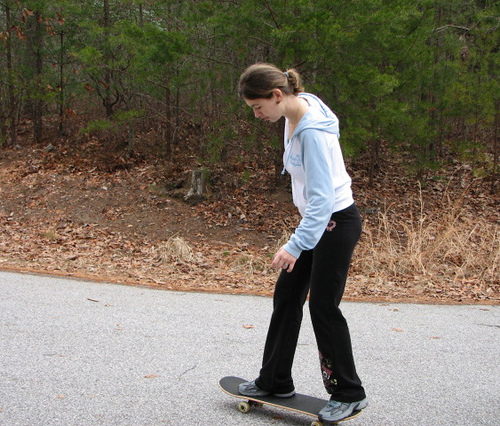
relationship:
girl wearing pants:
[235, 56, 417, 347] [228, 216, 402, 371]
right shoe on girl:
[235, 374, 294, 396] [235, 56, 365, 426]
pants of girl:
[253, 199, 372, 403] [235, 56, 365, 426]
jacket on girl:
[278, 92, 355, 257] [235, 56, 365, 426]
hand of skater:
[266, 241, 301, 276] [216, 371, 366, 424]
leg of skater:
[311, 226, 372, 412] [214, 62, 388, 421]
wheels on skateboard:
[234, 399, 324, 424] [219, 376, 361, 424]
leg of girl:
[236, 247, 310, 398] [235, 56, 365, 426]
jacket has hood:
[278, 92, 355, 257] [293, 90, 339, 136]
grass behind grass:
[0, 196, 496, 283] [0, 196, 496, 283]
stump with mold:
[172, 163, 209, 205] [198, 169, 201, 196]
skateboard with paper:
[219, 376, 361, 424] [218, 377, 331, 414]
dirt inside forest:
[36, 173, 208, 248] [2, 24, 234, 256]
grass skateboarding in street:
[0, 196, 496, 283] [2, 264, 499, 420]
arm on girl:
[271, 125, 333, 275] [235, 56, 365, 426]